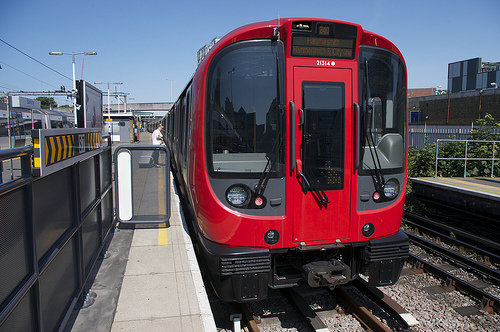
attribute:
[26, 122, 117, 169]
sign — black, yellow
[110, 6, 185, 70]
sky — blue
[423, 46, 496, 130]
building — red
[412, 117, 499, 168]
shrubbery — green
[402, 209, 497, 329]
train tracks — empty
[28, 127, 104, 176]
sign — gray, yellow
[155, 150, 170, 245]
paint — yellow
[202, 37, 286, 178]
window — large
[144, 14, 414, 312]
commuter train — red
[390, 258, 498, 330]
base — gravel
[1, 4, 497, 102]
sky — cloudless